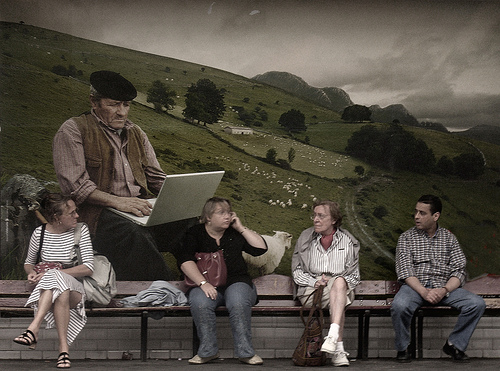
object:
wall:
[0, 0, 500, 297]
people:
[389, 193, 486, 362]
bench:
[0, 282, 499, 337]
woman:
[27, 193, 114, 363]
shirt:
[395, 221, 474, 301]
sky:
[1, 1, 500, 133]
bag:
[290, 311, 327, 368]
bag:
[181, 248, 228, 290]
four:
[10, 188, 499, 364]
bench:
[2, 300, 496, 365]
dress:
[21, 221, 96, 348]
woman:
[173, 195, 267, 365]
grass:
[3, 16, 498, 273]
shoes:
[321, 328, 354, 368]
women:
[292, 201, 362, 369]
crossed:
[313, 272, 362, 365]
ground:
[0, 352, 493, 370]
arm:
[177, 229, 219, 302]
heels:
[13, 326, 75, 368]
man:
[391, 194, 483, 362]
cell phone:
[227, 207, 238, 228]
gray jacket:
[290, 222, 363, 294]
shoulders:
[293, 233, 361, 257]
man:
[53, 66, 204, 285]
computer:
[102, 168, 224, 225]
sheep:
[298, 202, 309, 209]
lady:
[12, 193, 102, 366]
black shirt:
[173, 221, 268, 289]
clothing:
[118, 281, 187, 308]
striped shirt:
[290, 227, 364, 297]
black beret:
[88, 70, 138, 101]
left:
[311, 199, 339, 233]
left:
[412, 195, 441, 229]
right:
[196, 198, 235, 233]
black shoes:
[395, 341, 470, 363]